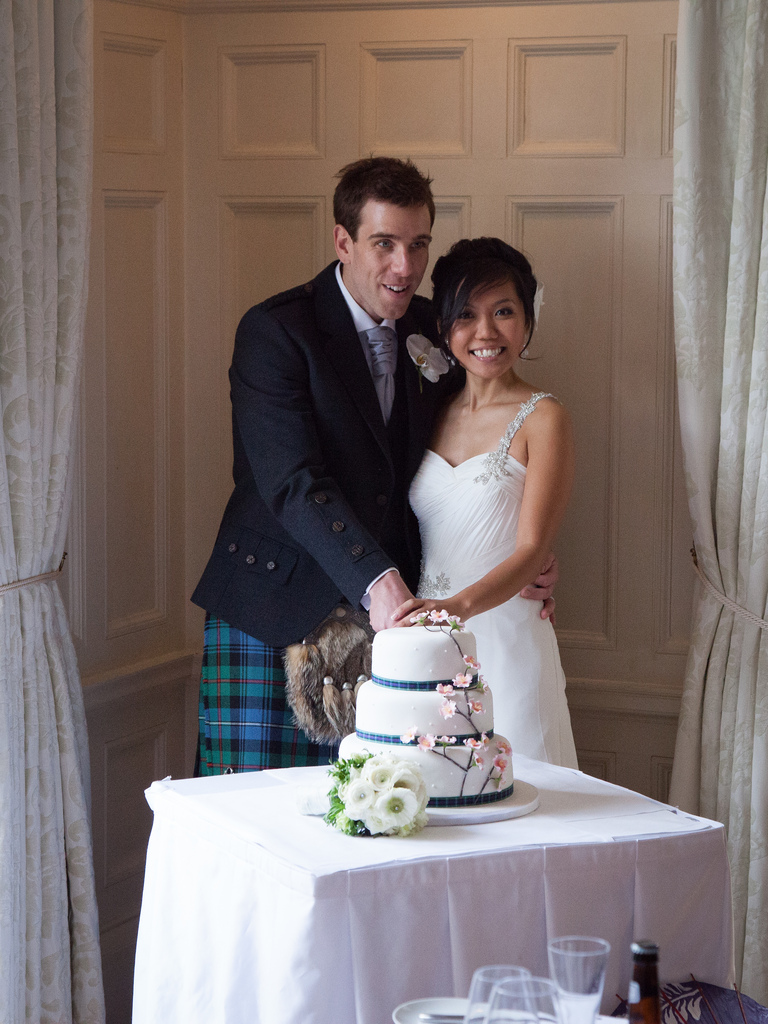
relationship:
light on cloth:
[253, 883, 314, 938] [119, 743, 758, 1022]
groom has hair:
[187, 161, 557, 779] [322, 148, 444, 237]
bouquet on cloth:
[323, 751, 432, 836] [129, 744, 732, 1021]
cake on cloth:
[334, 607, 540, 826] [129, 744, 732, 1021]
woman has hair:
[391, 237, 578, 766] [429, 231, 546, 317]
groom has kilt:
[187, 161, 557, 779] [183, 613, 311, 769]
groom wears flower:
[187, 161, 557, 779] [395, 325, 459, 389]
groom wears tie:
[187, 161, 557, 779] [359, 323, 403, 415]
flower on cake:
[448, 669, 475, 691] [334, 607, 540, 826]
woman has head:
[391, 237, 578, 766] [423, 228, 554, 387]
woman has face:
[391, 237, 578, 766] [437, 278, 534, 378]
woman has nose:
[391, 237, 578, 766] [470, 303, 497, 339]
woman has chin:
[409, 217, 573, 552] [465, 359, 512, 384]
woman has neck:
[391, 237, 578, 766] [454, 370, 526, 397]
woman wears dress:
[391, 237, 578, 766] [398, 387, 590, 761]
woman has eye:
[391, 237, 578, 766] [487, 298, 517, 325]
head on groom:
[338, 189, 431, 309] [187, 161, 557, 779]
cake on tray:
[334, 607, 540, 826] [398, 789, 537, 823]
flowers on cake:
[444, 636, 511, 796] [334, 607, 540, 826]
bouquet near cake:
[328, 757, 435, 837] [348, 616, 509, 804]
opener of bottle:
[629, 937, 661, 954] [623, 943, 666, 1021]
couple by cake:
[204, 150, 583, 769] [426, 249, 582, 760]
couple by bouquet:
[204, 150, 583, 769] [323, 751, 432, 836]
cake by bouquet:
[426, 249, 582, 760] [323, 751, 432, 836]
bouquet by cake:
[323, 751, 432, 836] [426, 249, 582, 760]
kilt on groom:
[202, 611, 322, 764] [186, 164, 442, 772]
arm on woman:
[519, 566, 566, 616] [391, 237, 578, 766]